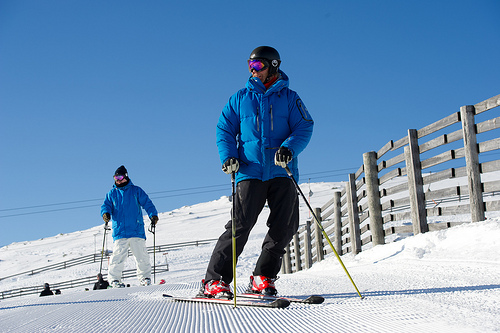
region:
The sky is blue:
[25, 95, 114, 169]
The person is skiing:
[154, 265, 350, 328]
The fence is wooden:
[360, 147, 499, 258]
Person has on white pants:
[111, 237, 170, 304]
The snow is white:
[53, 295, 105, 331]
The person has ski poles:
[143, 211, 191, 331]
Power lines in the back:
[4, 170, 223, 322]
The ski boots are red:
[247, 267, 294, 328]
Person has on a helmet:
[240, 32, 312, 124]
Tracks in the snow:
[33, 290, 198, 331]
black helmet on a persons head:
[248, 44, 280, 64]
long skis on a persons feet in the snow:
[162, 294, 324, 310]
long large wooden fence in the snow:
[280, 94, 499, 275]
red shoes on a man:
[202, 279, 276, 302]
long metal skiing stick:
[228, 173, 238, 310]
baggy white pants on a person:
[107, 237, 153, 282]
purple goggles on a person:
[250, 60, 267, 70]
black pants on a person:
[205, 177, 299, 279]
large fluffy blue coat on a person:
[215, 73, 315, 183]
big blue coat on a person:
[101, 185, 158, 239]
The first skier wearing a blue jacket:
[204, 27, 356, 322]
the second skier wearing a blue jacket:
[93, 155, 194, 296]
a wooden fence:
[307, 70, 493, 243]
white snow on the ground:
[32, 285, 172, 320]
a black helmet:
[246, 35, 289, 86]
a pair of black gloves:
[208, 148, 314, 186]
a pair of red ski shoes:
[186, 260, 301, 303]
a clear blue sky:
[43, 0, 188, 153]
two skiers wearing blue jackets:
[66, 28, 389, 299]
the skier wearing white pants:
[86, 140, 196, 292]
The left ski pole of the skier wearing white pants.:
[100, 215, 115, 293]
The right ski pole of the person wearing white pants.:
[148, 222, 162, 289]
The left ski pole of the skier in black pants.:
[222, 165, 244, 312]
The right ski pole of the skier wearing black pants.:
[287, 164, 372, 316]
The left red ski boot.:
[190, 274, 239, 301]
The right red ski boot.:
[250, 270, 277, 297]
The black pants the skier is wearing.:
[217, 172, 302, 287]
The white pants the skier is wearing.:
[102, 242, 154, 279]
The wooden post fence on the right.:
[242, 102, 499, 249]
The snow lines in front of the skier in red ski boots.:
[123, 285, 368, 332]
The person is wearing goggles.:
[209, 30, 377, 302]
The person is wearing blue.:
[172, 26, 338, 280]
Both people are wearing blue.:
[73, 40, 317, 297]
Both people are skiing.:
[66, 27, 381, 317]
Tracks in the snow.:
[65, 292, 302, 329]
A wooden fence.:
[353, 96, 495, 226]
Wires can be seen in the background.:
[6, 185, 97, 229]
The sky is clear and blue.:
[9, 6, 205, 156]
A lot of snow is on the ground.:
[20, 213, 438, 328]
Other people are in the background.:
[33, 254, 165, 314]